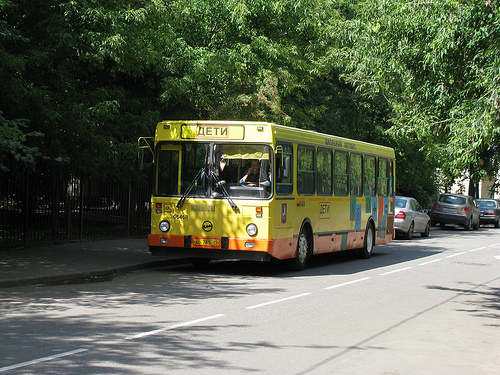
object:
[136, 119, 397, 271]
bus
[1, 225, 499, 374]
street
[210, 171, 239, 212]
wiper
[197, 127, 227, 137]
lettering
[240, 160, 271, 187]
person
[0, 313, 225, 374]
line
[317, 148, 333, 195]
window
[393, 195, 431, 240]
car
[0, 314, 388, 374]
shadow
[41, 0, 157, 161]
tree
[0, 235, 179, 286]
sidewalk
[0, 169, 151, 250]
fence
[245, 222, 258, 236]
light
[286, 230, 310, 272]
wheel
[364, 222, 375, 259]
wheel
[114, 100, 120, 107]
leaf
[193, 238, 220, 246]
plate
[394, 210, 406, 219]
light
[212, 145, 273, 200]
windshield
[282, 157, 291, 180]
mirror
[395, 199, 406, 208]
windshield